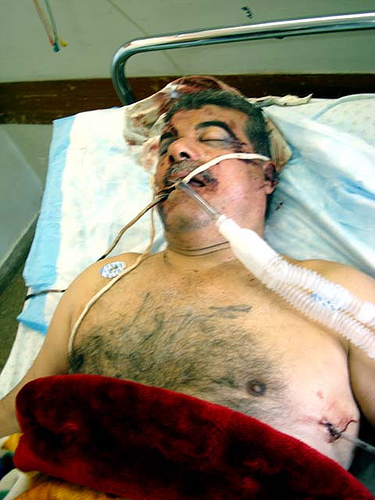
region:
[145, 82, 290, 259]
the head of a man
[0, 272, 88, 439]
the arm of a man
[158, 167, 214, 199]
the mouth of a man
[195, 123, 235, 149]
the eye of a man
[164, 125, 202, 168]
the nose of a man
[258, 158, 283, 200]
the ear of a man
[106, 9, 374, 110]
a gray metal bar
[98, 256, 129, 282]
a patch on the man's shoulder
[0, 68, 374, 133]
a brown wooden board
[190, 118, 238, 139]
the eyebrow of a man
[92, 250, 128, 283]
electrical lead patch on shoulder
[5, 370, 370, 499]
soft red bed restraint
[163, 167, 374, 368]
bendable breathing machine tube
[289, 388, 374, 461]
small inserted lung tube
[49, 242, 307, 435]
man's hairy chest with tattoo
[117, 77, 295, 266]
head of an injured man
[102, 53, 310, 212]
bloody towel under head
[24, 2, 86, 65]
different colored medical equipment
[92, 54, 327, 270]
man with head injury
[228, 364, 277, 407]
nipple of an older male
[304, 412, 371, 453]
tube going into his side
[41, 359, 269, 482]
red blanket covering the man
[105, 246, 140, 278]
man has sticky pads on arm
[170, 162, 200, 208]
man has a breathing tube in his mouth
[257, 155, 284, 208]
man's ear is covered in blood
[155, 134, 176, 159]
man has a black eye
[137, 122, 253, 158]
man has his eyes closed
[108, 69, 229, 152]
towel covered in blood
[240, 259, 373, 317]
two tubes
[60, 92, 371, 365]
man is in a hospital bed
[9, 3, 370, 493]
Man laying on a hospital bed.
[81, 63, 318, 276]
Man in pain.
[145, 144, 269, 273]
Breathing tube in man's mouth.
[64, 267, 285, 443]
The man has a hairy chest.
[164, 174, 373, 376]
The tube turns into two tubes.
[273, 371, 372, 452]
There is a tube inserted in his side.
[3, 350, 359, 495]
There is a red ring around the man's stomach.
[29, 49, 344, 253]
Apparently unconscious man.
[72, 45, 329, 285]
Bloody rag behind a man's head.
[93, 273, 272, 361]
Some sort of writing on the man's chest.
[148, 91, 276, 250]
a mans swollen battered head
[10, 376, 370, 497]
a red velvet fabric ring on a man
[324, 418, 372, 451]
a tube protruding from an injured mans abdomen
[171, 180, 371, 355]
a tube in a mans mouth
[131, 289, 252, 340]
a tattoo on a mans chest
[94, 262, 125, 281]
a sticker holding a device to mans chest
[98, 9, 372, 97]
a metal bar on a hospital bed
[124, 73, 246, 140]
a bloody cloth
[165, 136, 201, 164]
a mans nose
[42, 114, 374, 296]
a hospital cloth